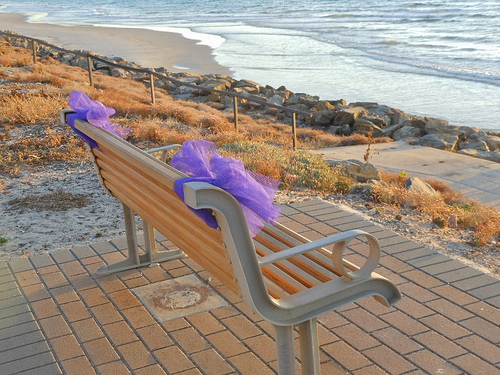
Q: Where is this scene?
A: The on beach.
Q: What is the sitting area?
A: A bench.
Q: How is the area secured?
A: A fence.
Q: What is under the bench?
A: A brick floor.